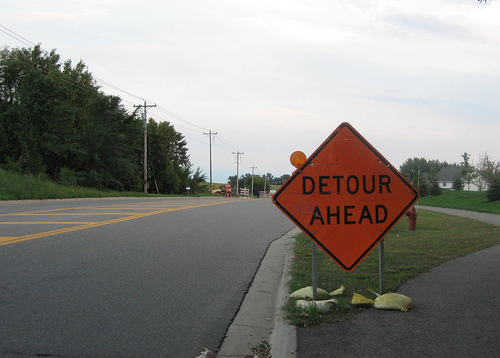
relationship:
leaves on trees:
[22, 100, 101, 140] [7, 39, 194, 189]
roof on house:
[435, 162, 493, 184] [435, 160, 492, 191]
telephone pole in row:
[127, 93, 159, 194] [129, 93, 274, 203]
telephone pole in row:
[225, 147, 246, 187] [129, 93, 274, 203]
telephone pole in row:
[245, 160, 260, 189] [129, 93, 274, 203]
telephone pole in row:
[260, 170, 276, 196] [129, 93, 274, 203]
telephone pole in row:
[198, 126, 223, 191] [129, 93, 274, 203]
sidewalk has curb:
[301, 188, 497, 352] [271, 233, 300, 355]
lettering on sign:
[301, 167, 396, 231] [269, 120, 422, 269]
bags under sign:
[303, 270, 491, 319] [262, 107, 444, 277]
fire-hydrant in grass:
[403, 203, 417, 230] [379, 226, 489, 276]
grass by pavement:
[303, 224, 442, 297] [165, 235, 284, 352]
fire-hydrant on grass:
[403, 203, 417, 230] [376, 227, 490, 283]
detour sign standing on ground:
[270, 121, 421, 273] [8, 287, 498, 355]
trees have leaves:
[6, 43, 192, 203] [22, 117, 77, 140]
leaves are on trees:
[22, 117, 77, 140] [6, 43, 192, 203]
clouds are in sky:
[387, 23, 477, 82] [7, 7, 498, 163]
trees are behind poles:
[6, 43, 192, 203] [135, 86, 215, 195]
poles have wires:
[135, 86, 215, 195] [149, 98, 209, 133]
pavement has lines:
[120, 235, 228, 352] [15, 201, 187, 239]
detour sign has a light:
[270, 121, 421, 273] [287, 145, 309, 170]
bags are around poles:
[295, 296, 337, 313] [305, 240, 392, 290]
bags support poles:
[295, 296, 337, 313] [305, 240, 392, 290]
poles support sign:
[305, 240, 392, 290] [269, 120, 422, 269]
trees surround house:
[405, 159, 498, 203] [437, 162, 486, 192]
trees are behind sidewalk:
[405, 159, 498, 203] [430, 197, 499, 230]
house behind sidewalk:
[437, 162, 486, 192] [430, 197, 499, 230]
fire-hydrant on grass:
[403, 200, 422, 235] [351, 177, 498, 250]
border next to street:
[209, 265, 266, 355] [18, 230, 139, 348]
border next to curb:
[209, 265, 266, 355] [279, 257, 295, 356]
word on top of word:
[299, 170, 392, 198] [305, 201, 391, 223]